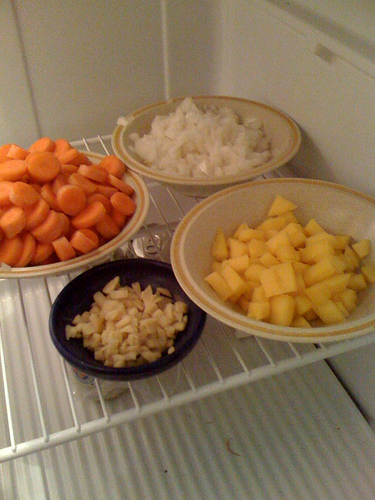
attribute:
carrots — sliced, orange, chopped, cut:
[0, 138, 136, 265]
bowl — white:
[1, 149, 151, 282]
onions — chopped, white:
[133, 99, 270, 180]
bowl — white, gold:
[114, 95, 304, 190]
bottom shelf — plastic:
[1, 282, 371, 496]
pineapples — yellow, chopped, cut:
[206, 198, 368, 327]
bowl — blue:
[49, 258, 204, 378]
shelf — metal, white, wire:
[1, 128, 373, 460]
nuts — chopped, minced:
[64, 277, 189, 365]